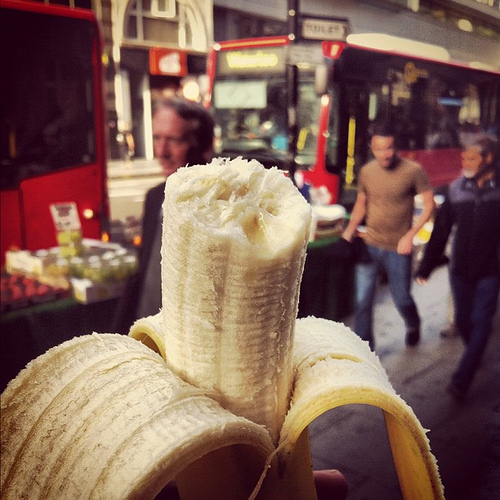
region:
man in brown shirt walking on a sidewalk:
[338, 125, 433, 346]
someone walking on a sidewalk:
[410, 133, 497, 399]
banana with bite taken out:
[163, 152, 313, 433]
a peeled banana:
[0, 157, 446, 498]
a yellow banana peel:
[0, 304, 442, 498]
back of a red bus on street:
[0, 0, 109, 267]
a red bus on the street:
[198, 30, 498, 200]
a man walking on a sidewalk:
[110, 91, 214, 332]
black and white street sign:
[282, 4, 351, 176]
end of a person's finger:
[313, 467, 351, 498]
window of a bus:
[33, 41, 85, 153]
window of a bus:
[226, 75, 273, 147]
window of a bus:
[289, 79, 327, 161]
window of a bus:
[333, 80, 373, 133]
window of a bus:
[386, 87, 416, 122]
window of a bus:
[420, 91, 442, 133]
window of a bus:
[435, 99, 465, 133]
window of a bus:
[455, 85, 471, 116]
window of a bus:
[468, 78, 493, 107]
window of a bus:
[478, 117, 498, 128]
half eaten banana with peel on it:
[0, 138, 450, 495]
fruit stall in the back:
[0, 208, 366, 363]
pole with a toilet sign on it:
[282, 0, 348, 207]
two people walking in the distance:
[332, 122, 498, 407]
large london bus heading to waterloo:
[197, 36, 499, 237]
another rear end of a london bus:
[0, 0, 115, 262]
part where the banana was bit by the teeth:
[162, 148, 315, 259]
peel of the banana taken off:
[0, 310, 452, 496]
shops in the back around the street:
[64, 0, 499, 156]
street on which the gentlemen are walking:
[242, 238, 498, 498]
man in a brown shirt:
[332, 123, 442, 345]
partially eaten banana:
[0, 152, 464, 493]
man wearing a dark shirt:
[417, 134, 498, 408]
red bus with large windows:
[207, 25, 498, 206]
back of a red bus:
[9, 2, 121, 246]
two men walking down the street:
[341, 127, 493, 389]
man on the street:
[112, 89, 223, 321]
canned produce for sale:
[3, 196, 143, 304]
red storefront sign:
[148, 42, 193, 81]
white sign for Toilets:
[288, 10, 355, 43]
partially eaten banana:
[138, 166, 330, 426]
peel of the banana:
[7, 302, 447, 499]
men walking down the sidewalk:
[134, 99, 499, 393]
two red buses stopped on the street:
[2, 0, 496, 275]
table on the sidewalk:
[3, 179, 356, 370]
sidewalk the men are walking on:
[303, 333, 495, 498]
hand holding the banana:
[155, 455, 347, 498]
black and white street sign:
[297, 12, 351, 49]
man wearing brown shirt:
[350, 124, 428, 339]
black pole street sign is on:
[277, 4, 305, 187]